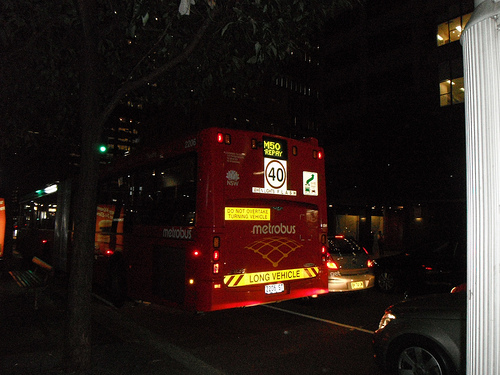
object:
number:
[269, 167, 284, 182]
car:
[321, 235, 381, 294]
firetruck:
[15, 124, 328, 315]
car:
[366, 253, 465, 301]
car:
[368, 284, 469, 374]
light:
[438, 79, 467, 106]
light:
[213, 250, 220, 260]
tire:
[382, 336, 459, 375]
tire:
[375, 271, 399, 292]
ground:
[406, 174, 463, 236]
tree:
[70, 165, 103, 369]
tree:
[0, 0, 359, 373]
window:
[435, 74, 469, 107]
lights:
[334, 200, 439, 220]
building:
[327, 7, 461, 244]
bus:
[3, 117, 332, 315]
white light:
[36, 183, 58, 197]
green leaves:
[226, 19, 281, 62]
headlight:
[375, 311, 395, 333]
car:
[323, 233, 376, 294]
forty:
[268, 166, 283, 181]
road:
[267, 304, 377, 335]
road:
[135, 313, 345, 364]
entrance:
[338, 214, 378, 236]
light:
[98, 145, 107, 153]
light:
[36, 183, 58, 197]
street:
[0, 212, 500, 374]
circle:
[265, 160, 285, 189]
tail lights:
[326, 258, 374, 270]